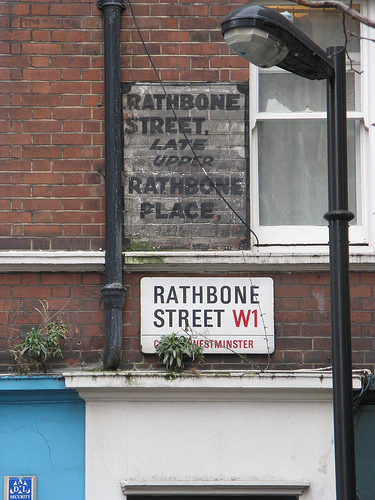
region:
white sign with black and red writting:
[138, 276, 275, 356]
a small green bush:
[9, 315, 67, 369]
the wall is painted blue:
[0, 377, 82, 497]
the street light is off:
[222, 5, 330, 86]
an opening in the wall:
[122, 480, 305, 499]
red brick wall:
[4, 3, 372, 364]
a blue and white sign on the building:
[3, 475, 36, 498]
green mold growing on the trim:
[124, 256, 167, 264]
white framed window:
[248, 5, 373, 248]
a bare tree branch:
[298, 1, 373, 27]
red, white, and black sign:
[134, 276, 286, 356]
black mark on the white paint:
[310, 443, 333, 478]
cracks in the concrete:
[9, 412, 77, 477]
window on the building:
[238, 3, 373, 249]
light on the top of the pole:
[214, 2, 338, 94]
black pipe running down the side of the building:
[96, 0, 135, 373]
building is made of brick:
[0, 0, 373, 406]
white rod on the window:
[259, 103, 358, 127]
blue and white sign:
[7, 473, 40, 499]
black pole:
[324, 34, 371, 496]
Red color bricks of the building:
[9, 30, 80, 186]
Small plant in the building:
[15, 308, 203, 378]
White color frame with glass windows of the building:
[265, 97, 360, 235]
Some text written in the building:
[125, 83, 244, 243]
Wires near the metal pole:
[357, 358, 372, 402]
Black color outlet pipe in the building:
[97, 2, 138, 281]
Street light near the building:
[160, 2, 371, 139]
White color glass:
[225, 31, 283, 72]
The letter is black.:
[150, 284, 166, 305]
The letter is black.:
[164, 284, 180, 306]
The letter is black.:
[178, 282, 190, 304]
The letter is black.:
[190, 283, 205, 306]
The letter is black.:
[206, 281, 219, 305]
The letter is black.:
[217, 281, 232, 306]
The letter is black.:
[231, 284, 248, 305]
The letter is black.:
[248, 280, 261, 305]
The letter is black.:
[151, 305, 167, 330]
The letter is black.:
[163, 307, 178, 328]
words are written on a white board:
[145, 280, 270, 363]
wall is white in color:
[129, 377, 271, 470]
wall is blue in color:
[12, 416, 80, 469]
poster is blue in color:
[7, 472, 40, 498]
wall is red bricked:
[16, 168, 80, 226]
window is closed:
[253, 104, 322, 220]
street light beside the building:
[238, 12, 374, 206]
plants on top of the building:
[17, 328, 206, 375]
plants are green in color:
[155, 336, 211, 363]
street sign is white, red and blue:
[140, 276, 273, 353]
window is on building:
[223, 2, 374, 317]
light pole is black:
[223, 3, 370, 499]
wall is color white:
[84, 377, 335, 499]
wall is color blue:
[4, 376, 88, 497]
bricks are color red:
[2, 1, 258, 371]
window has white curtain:
[259, 6, 355, 225]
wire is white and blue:
[318, 366, 373, 396]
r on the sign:
[123, 92, 135, 103]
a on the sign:
[170, 282, 180, 306]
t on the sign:
[175, 280, 195, 306]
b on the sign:
[208, 282, 219, 300]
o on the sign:
[220, 285, 231, 307]